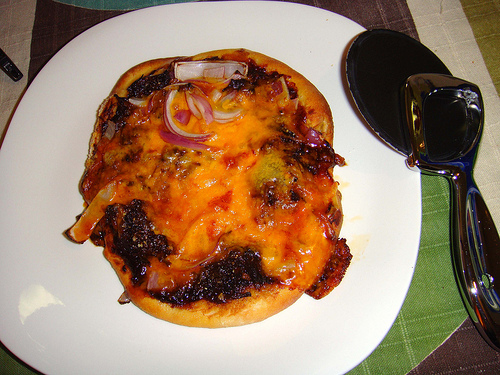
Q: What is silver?
A: Spoon.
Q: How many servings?
A: One.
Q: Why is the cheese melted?
A: It was baked.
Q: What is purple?
A: Onion.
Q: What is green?
A: Placemat.